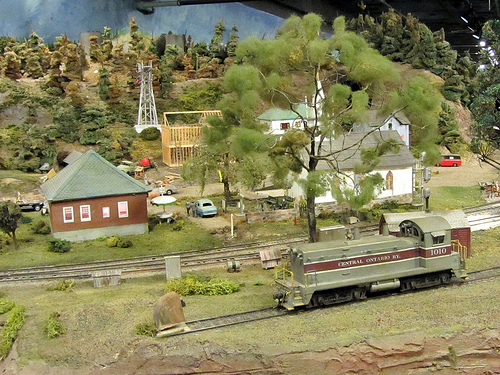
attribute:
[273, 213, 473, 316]
train — green, here, brown, alone, model, small, green`, parked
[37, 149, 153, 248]
house — brown, green, small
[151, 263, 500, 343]
spur — here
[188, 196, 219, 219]
car — blue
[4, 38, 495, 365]
ground — green, brown, here, sparse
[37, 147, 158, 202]
roof — green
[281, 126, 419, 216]
church — white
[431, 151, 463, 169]
van — red, small, parked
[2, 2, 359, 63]
sky — blue, painted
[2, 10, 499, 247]
trees — scattered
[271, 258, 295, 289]
part — yellow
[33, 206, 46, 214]
part — here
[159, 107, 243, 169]
frame — unfinished, house, unfinishe3d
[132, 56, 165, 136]
tower — steel, white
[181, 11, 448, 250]
oak — large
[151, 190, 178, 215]
umbrella — green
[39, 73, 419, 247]
town — model, small, here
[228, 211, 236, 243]
post — white, wooden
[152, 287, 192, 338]
stop — brown